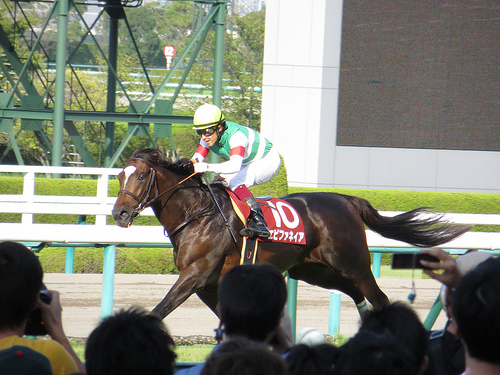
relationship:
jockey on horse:
[185, 101, 283, 245] [112, 144, 473, 325]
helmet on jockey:
[188, 102, 228, 135] [185, 101, 283, 245]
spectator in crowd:
[218, 266, 291, 343] [3, 238, 499, 373]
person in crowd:
[86, 305, 175, 374] [3, 238, 499, 373]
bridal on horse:
[116, 167, 160, 226] [112, 144, 473, 325]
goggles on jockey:
[198, 124, 223, 139] [185, 101, 283, 245]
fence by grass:
[2, 223, 497, 339] [4, 175, 499, 271]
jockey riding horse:
[185, 101, 283, 245] [112, 144, 473, 325]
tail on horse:
[346, 191, 472, 247] [112, 144, 473, 325]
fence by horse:
[2, 223, 497, 339] [112, 144, 473, 325]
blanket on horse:
[223, 188, 311, 248] [112, 144, 473, 325]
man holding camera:
[0, 238, 86, 374] [20, 284, 57, 338]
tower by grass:
[0, 0, 230, 179] [4, 175, 499, 271]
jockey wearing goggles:
[185, 101, 283, 245] [198, 124, 223, 139]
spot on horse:
[119, 162, 138, 192] [112, 144, 473, 325]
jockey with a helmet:
[185, 101, 283, 245] [188, 102, 228, 135]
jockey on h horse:
[185, 101, 283, 245] [112, 144, 473, 325]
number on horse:
[265, 197, 303, 232] [112, 144, 473, 325]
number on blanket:
[265, 197, 303, 232] [223, 188, 311, 248]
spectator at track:
[218, 266, 291, 343] [41, 267, 461, 334]